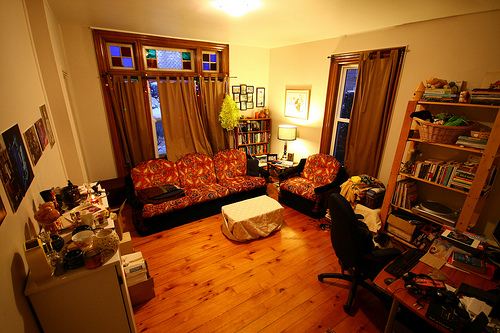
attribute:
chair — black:
[315, 190, 407, 316]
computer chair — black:
[319, 189, 403, 317]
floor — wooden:
[117, 175, 415, 331]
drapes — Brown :
[151, 57, 207, 175]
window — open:
[147, 77, 195, 155]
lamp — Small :
[271, 122, 301, 157]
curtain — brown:
[345, 59, 394, 176]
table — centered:
[211, 194, 294, 239]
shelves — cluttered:
[374, 87, 499, 247]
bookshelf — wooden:
[373, 97, 498, 257]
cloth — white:
[205, 168, 287, 260]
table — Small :
[223, 192, 274, 229]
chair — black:
[330, 200, 350, 254]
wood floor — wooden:
[165, 237, 338, 328]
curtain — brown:
[108, 80, 161, 171]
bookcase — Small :
[252, 117, 286, 178]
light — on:
[214, 0, 256, 17]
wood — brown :
[112, 179, 433, 331]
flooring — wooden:
[115, 184, 384, 332]